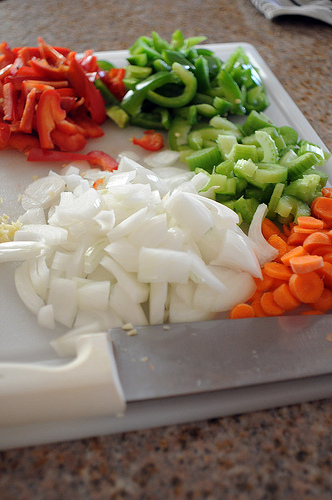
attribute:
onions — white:
[6, 154, 279, 330]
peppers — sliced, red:
[7, 37, 115, 168]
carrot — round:
[259, 189, 330, 308]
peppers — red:
[110, 24, 276, 106]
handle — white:
[0, 329, 126, 424]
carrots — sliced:
[240, 202, 329, 311]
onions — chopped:
[16, 186, 217, 322]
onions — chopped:
[4, 162, 282, 346]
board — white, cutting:
[4, 45, 324, 339]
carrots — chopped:
[229, 185, 331, 322]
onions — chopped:
[39, 148, 269, 319]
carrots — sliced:
[232, 177, 320, 312]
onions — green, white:
[5, 157, 258, 327]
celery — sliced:
[251, 165, 295, 180]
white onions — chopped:
[34, 184, 230, 298]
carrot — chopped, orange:
[287, 255, 321, 272]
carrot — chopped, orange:
[288, 270, 323, 304]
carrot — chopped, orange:
[270, 282, 299, 311]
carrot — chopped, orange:
[312, 193, 331, 220]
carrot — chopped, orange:
[268, 232, 288, 260]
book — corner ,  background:
[251, 0, 331, 28]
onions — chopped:
[54, 166, 236, 295]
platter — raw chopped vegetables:
[0, 13, 330, 396]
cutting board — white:
[234, 39, 301, 132]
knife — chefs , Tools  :
[0, 306, 329, 414]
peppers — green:
[92, 25, 274, 124]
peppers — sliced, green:
[109, 30, 270, 122]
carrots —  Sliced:
[269, 203, 326, 290]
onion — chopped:
[5, 150, 279, 354]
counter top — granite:
[167, 436, 322, 492]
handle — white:
[2, 334, 114, 424]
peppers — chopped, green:
[5, 42, 231, 128]